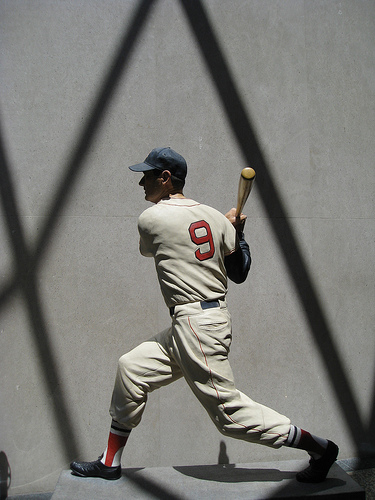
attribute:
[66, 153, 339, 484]
baseball player — standing, small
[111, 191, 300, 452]
uniform — white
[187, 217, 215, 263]
number — red, 9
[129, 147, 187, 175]
cap — black, blue, gray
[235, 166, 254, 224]
bat — wooden, light brown, brown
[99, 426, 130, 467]
sock — white, red, blue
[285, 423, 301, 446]
sock — white, red, blue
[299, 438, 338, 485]
shoe — black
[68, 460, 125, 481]
shoe — black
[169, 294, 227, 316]
belt — gray, blue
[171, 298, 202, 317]
buckle — white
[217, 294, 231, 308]
buckle — white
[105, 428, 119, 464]
line — red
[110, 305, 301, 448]
pants — white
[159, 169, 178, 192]
ear — small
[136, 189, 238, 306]
shirt — white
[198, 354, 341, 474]
leg — back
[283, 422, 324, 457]
heel — lifted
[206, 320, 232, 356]
pocket — back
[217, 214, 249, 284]
sleeve — black